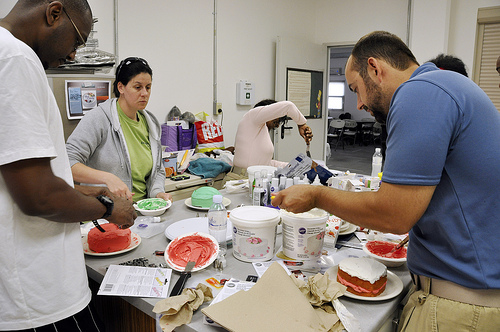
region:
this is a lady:
[92, 53, 169, 163]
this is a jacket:
[74, 118, 115, 152]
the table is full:
[156, 165, 289, 295]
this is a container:
[226, 206, 280, 256]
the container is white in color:
[226, 203, 279, 258]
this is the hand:
[383, 116, 439, 186]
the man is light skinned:
[380, 193, 408, 223]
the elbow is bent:
[275, 95, 297, 116]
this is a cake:
[87, 228, 127, 254]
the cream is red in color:
[173, 239, 200, 259]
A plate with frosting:
[165, 232, 218, 270]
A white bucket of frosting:
[230, 205, 280, 259]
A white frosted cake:
[337, 255, 388, 295]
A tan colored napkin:
[152, 283, 211, 330]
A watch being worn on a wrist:
[97, 193, 115, 216]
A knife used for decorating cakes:
[303, 126, 312, 156]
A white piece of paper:
[96, 263, 172, 297]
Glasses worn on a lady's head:
[118, 57, 145, 69]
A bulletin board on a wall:
[285, 65, 325, 118]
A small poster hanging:
[65, 80, 110, 117]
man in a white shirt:
[1, 0, 117, 328]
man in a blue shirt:
[266, 31, 498, 330]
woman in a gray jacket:
[66, 55, 172, 201]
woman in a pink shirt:
[222, 98, 314, 183]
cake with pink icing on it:
[85, 219, 132, 253]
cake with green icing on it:
[187, 185, 221, 210]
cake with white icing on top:
[334, 256, 389, 297]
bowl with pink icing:
[166, 230, 219, 270]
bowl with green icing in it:
[133, 194, 170, 216]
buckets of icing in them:
[230, 202, 330, 262]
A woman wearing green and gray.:
[66, 54, 171, 199]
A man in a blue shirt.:
[270, 30, 499, 330]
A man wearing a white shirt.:
[0, 0, 137, 330]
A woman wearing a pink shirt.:
[228, 96, 314, 180]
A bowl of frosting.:
[163, 227, 219, 274]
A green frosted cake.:
[185, 183, 232, 209]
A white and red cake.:
[324, 256, 402, 306]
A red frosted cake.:
[86, 214, 136, 258]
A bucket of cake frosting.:
[229, 206, 278, 262]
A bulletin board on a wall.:
[284, 68, 323, 117]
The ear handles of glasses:
[60, 9, 85, 44]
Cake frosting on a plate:
[165, 233, 215, 269]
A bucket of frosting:
[230, 205, 280, 260]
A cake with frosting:
[335, 255, 385, 292]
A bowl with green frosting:
[130, 195, 165, 210]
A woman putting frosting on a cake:
[235, 97, 310, 167]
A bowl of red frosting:
[365, 236, 405, 261]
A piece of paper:
[97, 265, 169, 295]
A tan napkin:
[153, 283, 213, 330]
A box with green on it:
[235, 80, 255, 105]